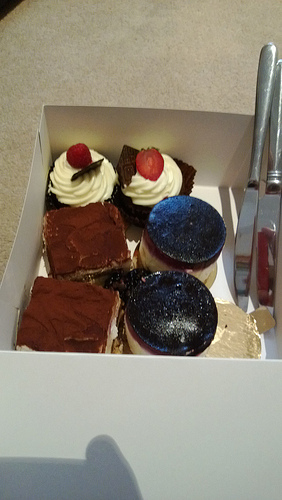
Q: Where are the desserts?
A: Box.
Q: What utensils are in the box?
A: Knives.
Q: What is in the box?
A: Pastries.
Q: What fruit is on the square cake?
A: Strawberry.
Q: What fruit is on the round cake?
A: Raspberry.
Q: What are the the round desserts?
A: Berry cheesecake.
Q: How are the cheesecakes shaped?
A: Round.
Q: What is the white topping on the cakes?
A: Cream.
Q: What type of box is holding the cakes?
A: White cardboard.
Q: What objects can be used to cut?
A: Knives.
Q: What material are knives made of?
A: Metal.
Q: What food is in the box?
A: Pastries.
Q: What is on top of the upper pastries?
A: Strawberries.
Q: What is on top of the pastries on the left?
A: Chocolate.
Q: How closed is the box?
A: It is open.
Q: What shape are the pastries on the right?
A: Round.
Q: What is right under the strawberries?
A: Whipped cream.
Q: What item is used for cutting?
A: Knife.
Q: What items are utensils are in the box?
A: Knives.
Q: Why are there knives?
A: To cut the pastries.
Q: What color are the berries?
A: Red.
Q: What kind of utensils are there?
A: Knives.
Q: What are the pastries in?
A: Box.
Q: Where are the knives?
A: In the box.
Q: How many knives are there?
A: Two.